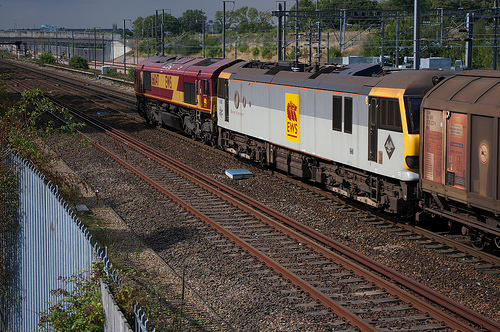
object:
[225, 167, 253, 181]
box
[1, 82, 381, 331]
tracks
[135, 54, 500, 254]
train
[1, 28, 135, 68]
bridge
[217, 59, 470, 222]
train car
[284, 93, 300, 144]
sign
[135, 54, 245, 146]
train car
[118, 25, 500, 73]
cliff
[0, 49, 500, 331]
ground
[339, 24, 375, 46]
wires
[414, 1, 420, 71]
pole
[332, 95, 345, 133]
windows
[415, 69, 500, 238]
train car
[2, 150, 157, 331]
fence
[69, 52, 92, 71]
trees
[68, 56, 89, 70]
bush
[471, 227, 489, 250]
wheels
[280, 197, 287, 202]
rock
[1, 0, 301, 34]
sky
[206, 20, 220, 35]
building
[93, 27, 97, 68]
post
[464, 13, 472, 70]
poles